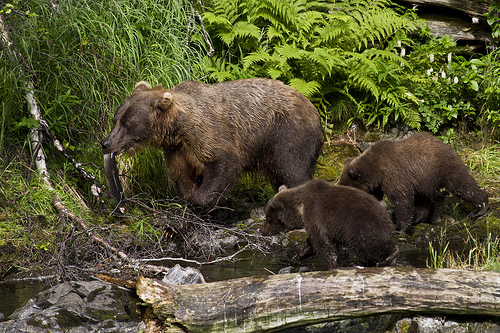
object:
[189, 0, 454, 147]
vegetation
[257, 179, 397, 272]
bear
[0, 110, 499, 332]
ground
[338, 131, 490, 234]
cubs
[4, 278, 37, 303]
water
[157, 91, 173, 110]
ear top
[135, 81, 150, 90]
ear top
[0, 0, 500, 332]
scene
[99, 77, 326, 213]
bear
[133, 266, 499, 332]
log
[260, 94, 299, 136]
bear's fur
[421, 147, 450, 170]
bear's fur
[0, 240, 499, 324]
river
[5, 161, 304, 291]
branch